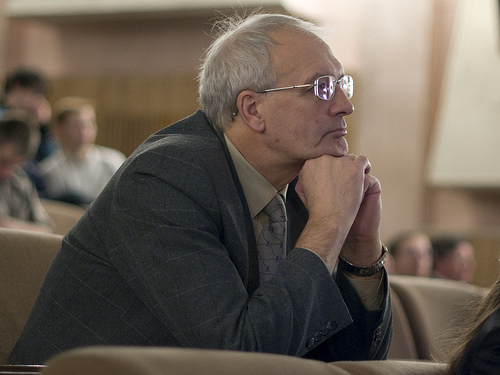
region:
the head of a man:
[196, 22, 413, 174]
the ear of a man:
[222, 75, 275, 128]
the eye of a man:
[291, 65, 361, 105]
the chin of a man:
[321, 136, 372, 173]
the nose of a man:
[324, 93, 368, 125]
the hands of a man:
[286, 151, 391, 228]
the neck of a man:
[211, 103, 306, 225]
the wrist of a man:
[254, 172, 392, 302]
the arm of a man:
[86, 160, 396, 348]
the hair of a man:
[187, 15, 350, 150]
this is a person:
[14, 10, 411, 372]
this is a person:
[57, 85, 131, 200]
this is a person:
[2, 45, 67, 211]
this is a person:
[0, 127, 52, 244]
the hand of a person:
[262, 148, 372, 338]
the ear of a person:
[234, 82, 283, 143]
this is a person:
[429, 225, 482, 294]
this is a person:
[381, 215, 439, 278]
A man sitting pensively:
[19, 6, 414, 368]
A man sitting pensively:
[21, 5, 401, 365]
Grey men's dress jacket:
[4, 107, 394, 374]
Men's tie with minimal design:
[256, 193, 288, 290]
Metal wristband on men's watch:
[337, 242, 388, 278]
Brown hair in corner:
[430, 260, 499, 374]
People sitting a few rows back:
[0, 69, 131, 231]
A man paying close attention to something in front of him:
[5, 11, 395, 363]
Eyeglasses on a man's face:
[231, 71, 354, 116]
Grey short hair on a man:
[190, 0, 317, 137]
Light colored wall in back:
[0, 0, 497, 238]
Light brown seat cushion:
[1, 226, 64, 360]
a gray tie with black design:
[249, 189, 290, 291]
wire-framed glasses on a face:
[231, 73, 354, 116]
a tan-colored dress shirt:
[220, 130, 287, 220]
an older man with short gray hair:
[196, 9, 351, 156]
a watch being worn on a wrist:
[338, 240, 390, 279]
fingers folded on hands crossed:
[293, 154, 383, 243]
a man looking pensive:
[301, 25, 354, 157]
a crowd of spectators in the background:
[1, 60, 97, 175]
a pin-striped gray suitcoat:
[24, 108, 354, 361]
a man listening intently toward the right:
[199, 13, 354, 159]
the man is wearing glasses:
[89, 11, 391, 345]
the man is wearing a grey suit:
[68, 20, 403, 362]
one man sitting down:
[124, 8, 393, 361]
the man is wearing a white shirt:
[45, 95, 108, 194]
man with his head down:
[0, 105, 54, 235]